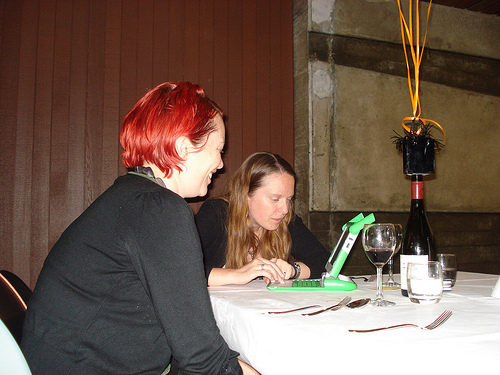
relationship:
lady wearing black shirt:
[20, 83, 260, 375] [21, 165, 243, 374]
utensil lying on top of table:
[301, 295, 351, 316] [198, 265, 499, 373]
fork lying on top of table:
[347, 306, 454, 334] [198, 265, 499, 373]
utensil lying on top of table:
[260, 302, 324, 314] [198, 265, 499, 373]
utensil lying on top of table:
[300, 295, 370, 316] [198, 265, 499, 373]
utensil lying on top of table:
[349, 274, 377, 282] [198, 265, 499, 373]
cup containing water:
[403, 261, 443, 305] [404, 278, 444, 297]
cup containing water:
[435, 251, 457, 287] [440, 265, 456, 287]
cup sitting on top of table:
[403, 261, 443, 305] [198, 265, 499, 373]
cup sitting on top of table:
[435, 251, 457, 287] [198, 265, 499, 373]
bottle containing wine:
[398, 174, 435, 292] [399, 176, 451, 290]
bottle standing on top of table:
[398, 174, 435, 292] [232, 266, 492, 364]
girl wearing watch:
[195, 152, 335, 288] [282, 255, 304, 281]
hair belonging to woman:
[236, 147, 301, 182] [228, 147, 303, 248]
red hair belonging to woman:
[122, 81, 224, 179] [19, 78, 235, 373]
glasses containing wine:
[361, 223, 396, 306] [365, 247, 395, 267]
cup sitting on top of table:
[407, 261, 443, 305] [226, 258, 499, 345]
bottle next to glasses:
[398, 174, 435, 292] [361, 223, 396, 306]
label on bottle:
[397, 250, 431, 290] [400, 172, 444, 297]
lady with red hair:
[14, 78, 265, 373] [119, 81, 224, 179]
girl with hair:
[195, 152, 335, 288] [224, 150, 294, 268]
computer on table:
[267, 211, 376, 289] [198, 265, 499, 373]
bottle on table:
[398, 174, 435, 292] [198, 265, 499, 373]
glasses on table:
[361, 223, 396, 306] [324, 337, 440, 360]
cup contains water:
[407, 261, 443, 305] [405, 276, 443, 295]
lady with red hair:
[20, 83, 260, 375] [122, 81, 224, 179]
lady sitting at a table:
[20, 83, 260, 375] [209, 252, 499, 372]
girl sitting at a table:
[195, 152, 335, 288] [209, 252, 499, 372]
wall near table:
[1, 1, 497, 287] [198, 232, 490, 304]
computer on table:
[267, 205, 377, 295] [198, 265, 499, 373]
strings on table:
[371, 0, 452, 145] [206, 271, 497, 371]